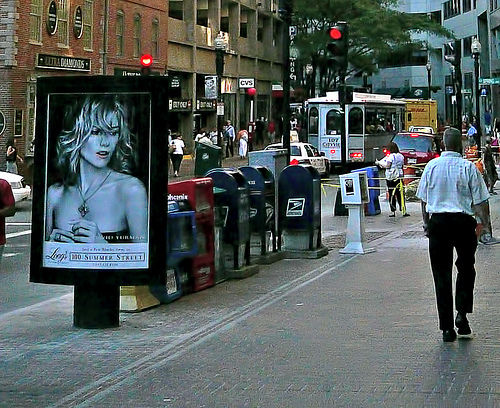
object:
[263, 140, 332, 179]
cab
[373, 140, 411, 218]
woman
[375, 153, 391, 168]
newspaper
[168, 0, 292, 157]
buildings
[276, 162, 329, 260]
mail box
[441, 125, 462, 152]
short hair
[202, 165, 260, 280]
mailbox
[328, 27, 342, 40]
red light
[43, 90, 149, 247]
woman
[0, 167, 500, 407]
ground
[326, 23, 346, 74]
light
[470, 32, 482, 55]
light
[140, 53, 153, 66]
light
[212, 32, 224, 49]
light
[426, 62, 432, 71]
light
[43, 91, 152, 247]
woman's photo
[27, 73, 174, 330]
advertisement board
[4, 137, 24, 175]
person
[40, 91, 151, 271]
poster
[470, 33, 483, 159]
lamp post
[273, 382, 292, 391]
bricks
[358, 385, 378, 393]
bricks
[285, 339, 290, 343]
bricks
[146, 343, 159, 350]
bricks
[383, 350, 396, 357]
bricks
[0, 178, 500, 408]
cobblestone street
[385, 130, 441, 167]
red van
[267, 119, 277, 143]
person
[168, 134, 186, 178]
person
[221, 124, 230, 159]
person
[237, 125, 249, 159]
person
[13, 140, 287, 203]
sidewalk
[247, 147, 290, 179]
post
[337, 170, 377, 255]
newstand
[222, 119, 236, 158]
people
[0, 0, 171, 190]
building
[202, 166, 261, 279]
mail post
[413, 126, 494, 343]
man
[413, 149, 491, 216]
shirt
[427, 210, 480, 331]
pants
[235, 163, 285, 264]
mailbox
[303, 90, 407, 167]
trolley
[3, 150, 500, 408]
road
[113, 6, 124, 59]
windows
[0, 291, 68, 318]
curb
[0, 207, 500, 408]
sidewalk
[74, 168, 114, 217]
necklace